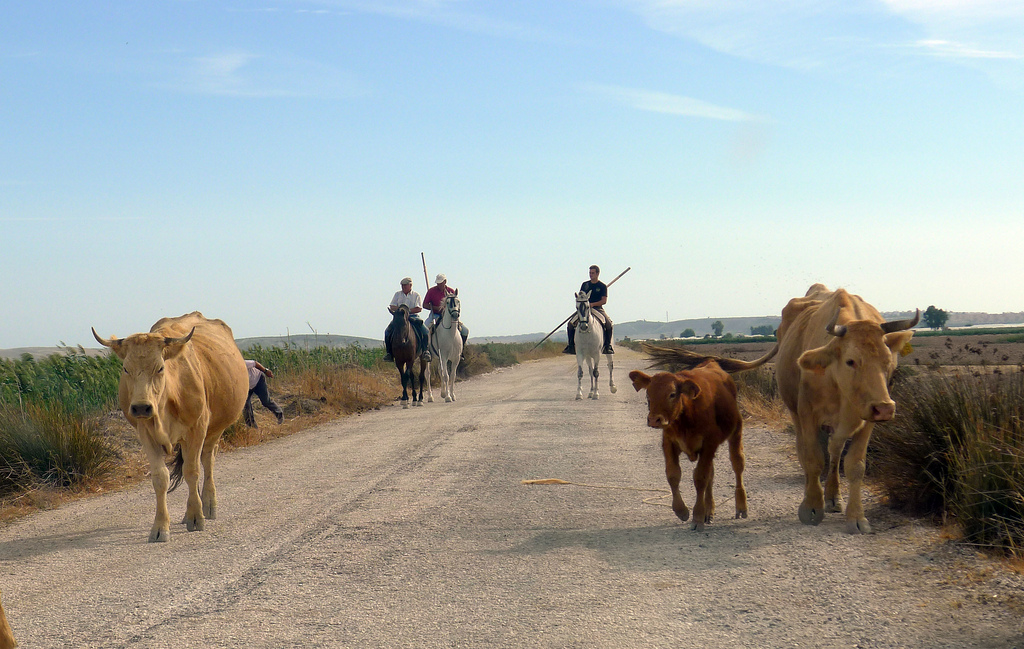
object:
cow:
[88, 310, 249, 542]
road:
[0, 344, 1024, 649]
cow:
[640, 284, 920, 535]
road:
[638, 283, 918, 536]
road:
[539, 343, 648, 390]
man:
[529, 264, 630, 400]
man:
[424, 273, 471, 402]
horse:
[429, 288, 464, 403]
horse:
[384, 303, 430, 409]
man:
[386, 277, 427, 409]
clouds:
[143, 38, 315, 96]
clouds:
[394, 32, 522, 132]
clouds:
[592, 84, 754, 124]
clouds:
[829, 182, 925, 244]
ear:
[797, 336, 836, 369]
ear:
[882, 331, 915, 353]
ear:
[685, 380, 702, 400]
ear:
[629, 370, 651, 393]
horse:
[570, 290, 617, 401]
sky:
[2, 0, 1023, 348]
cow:
[629, 283, 920, 533]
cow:
[629, 353, 744, 532]